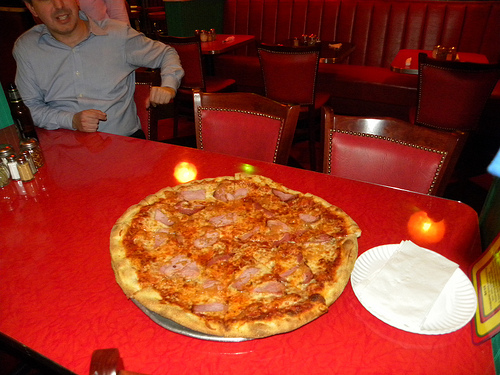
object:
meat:
[251, 275, 283, 292]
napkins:
[369, 239, 459, 319]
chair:
[256, 43, 333, 171]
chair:
[408, 52, 494, 138]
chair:
[162, 34, 237, 143]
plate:
[349, 242, 478, 352]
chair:
[321, 107, 466, 198]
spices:
[0, 131, 43, 188]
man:
[13, 0, 186, 139]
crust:
[105, 171, 357, 337]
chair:
[192, 88, 301, 166]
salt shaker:
[6, 154, 20, 179]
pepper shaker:
[15, 156, 36, 182]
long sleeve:
[14, 10, 185, 132]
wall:
[221, 4, 496, 72]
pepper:
[17, 137, 44, 167]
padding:
[324, 128, 444, 189]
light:
[174, 154, 197, 184]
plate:
[150, 312, 171, 326]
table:
[0, 104, 479, 375]